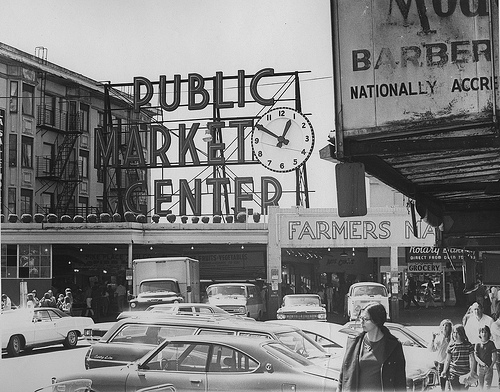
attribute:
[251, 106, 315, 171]
clock — large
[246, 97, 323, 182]
clock — large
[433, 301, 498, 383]
children — walking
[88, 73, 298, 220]
sign — large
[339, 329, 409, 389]
coat — dark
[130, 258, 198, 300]
truck — parked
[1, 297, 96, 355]
car — white, parked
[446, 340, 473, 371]
shirt — striped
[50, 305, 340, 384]
cars — parked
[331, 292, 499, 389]
people — leaving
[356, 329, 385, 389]
shirt — dark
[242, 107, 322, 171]
clock — white